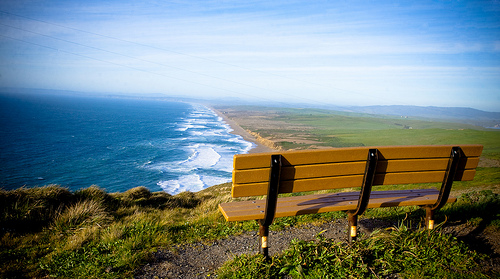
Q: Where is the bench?
A: The beach.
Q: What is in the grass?
A: Bench.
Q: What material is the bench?
A: Wood.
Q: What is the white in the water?
A: Foam.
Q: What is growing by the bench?
A: Grass.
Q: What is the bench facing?
A: Sea.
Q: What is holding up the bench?
A: Metal.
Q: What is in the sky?
A: Clouds.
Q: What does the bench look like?
A: Brown.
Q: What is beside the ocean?
A: Grass.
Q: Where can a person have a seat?
A: On the bench.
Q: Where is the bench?
A: On a cliff.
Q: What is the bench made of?
A: Wood and metal.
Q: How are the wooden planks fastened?
A: With screws.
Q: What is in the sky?
A: Sparse clouds.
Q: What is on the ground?
A: Undulating grass.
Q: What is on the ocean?
A: Waves.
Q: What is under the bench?
A: Gravel.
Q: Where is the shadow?
A: Under the bench.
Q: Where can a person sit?
A: Bench.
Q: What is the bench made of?
A: Wood.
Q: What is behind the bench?
A: Grass.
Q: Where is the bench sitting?
A: Hill above the shore.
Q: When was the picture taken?
A: Daytime.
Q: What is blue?
A: Ocean.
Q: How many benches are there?
A: One.